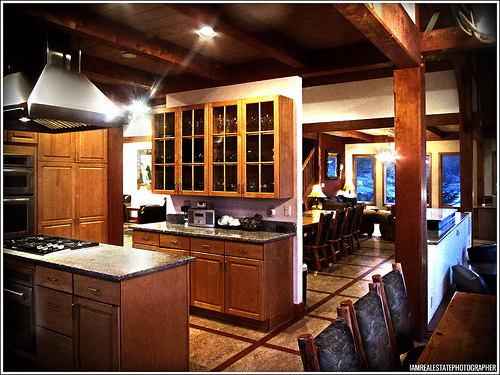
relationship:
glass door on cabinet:
[202, 112, 294, 177] [149, 92, 293, 199]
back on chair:
[295, 303, 363, 374] [298, 304, 368, 371]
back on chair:
[295, 304, 363, 370] [294, 304, 362, 373]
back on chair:
[385, 273, 416, 342] [370, 262, 425, 374]